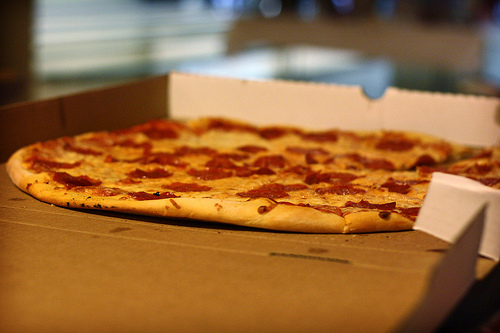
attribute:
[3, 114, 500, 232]
pizza — greasy, large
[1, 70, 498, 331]
box — greasy, open, brown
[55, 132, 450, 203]
pepperoni — red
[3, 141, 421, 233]
crust — light brown, well done, thin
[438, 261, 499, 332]
counter — wooden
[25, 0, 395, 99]
window — open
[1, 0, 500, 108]
room — blurry